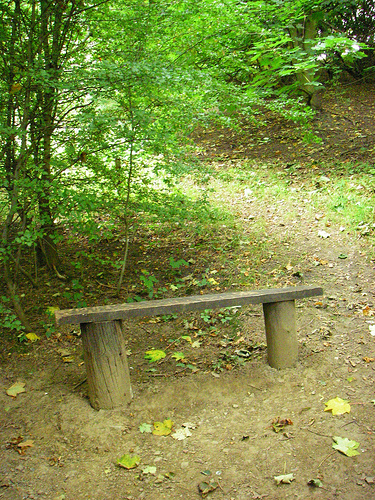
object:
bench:
[54, 285, 323, 410]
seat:
[54, 283, 323, 325]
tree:
[0, 0, 114, 334]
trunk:
[13, 2, 71, 291]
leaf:
[115, 451, 142, 469]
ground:
[0, 107, 374, 499]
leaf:
[167, 258, 190, 271]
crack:
[97, 356, 116, 409]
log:
[80, 318, 134, 410]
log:
[262, 293, 298, 371]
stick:
[93, 272, 145, 298]